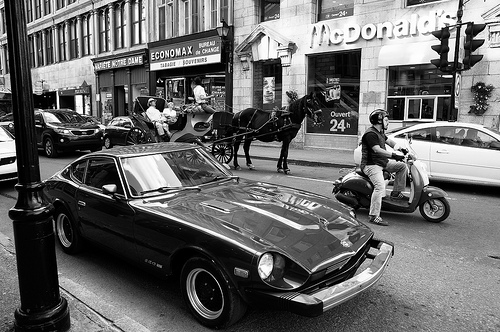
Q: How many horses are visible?
A: One.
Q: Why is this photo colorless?
A: Black and white filter.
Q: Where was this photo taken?
A: On a crowded street.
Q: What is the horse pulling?
A: A carriage.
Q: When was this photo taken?
A: Outside, during the daytime.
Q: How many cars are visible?
A: Five.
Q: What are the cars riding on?
A: A street.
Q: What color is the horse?
A: Black.